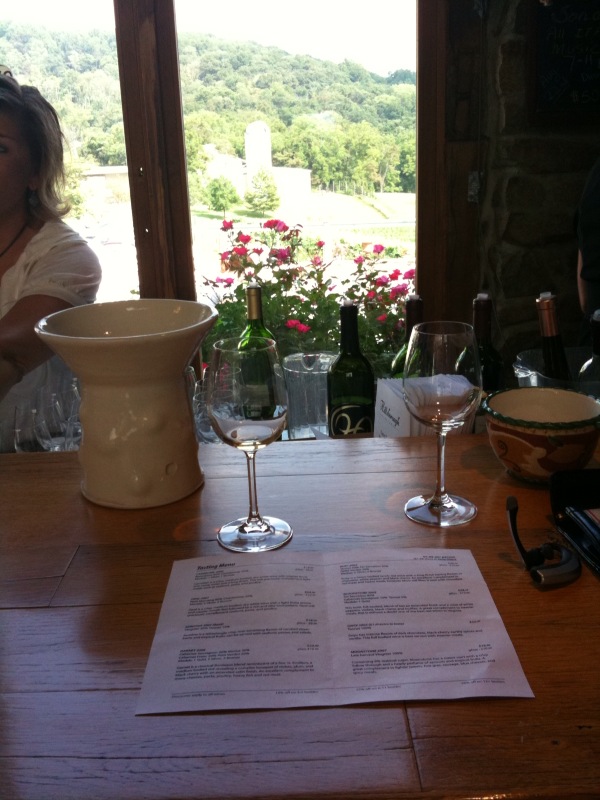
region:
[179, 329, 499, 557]
Wine glasses on table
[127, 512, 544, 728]
Wine menu on the table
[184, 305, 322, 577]
Wine glass on the table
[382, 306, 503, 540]
Wine glass on the table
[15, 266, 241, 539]
Spit bucket on the table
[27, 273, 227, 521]
White spit bucket on table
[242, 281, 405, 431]
bottles of wine behind glasses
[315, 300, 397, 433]
bottle of wine with black label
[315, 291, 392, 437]
bottle of wine behind glasses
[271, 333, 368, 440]
Pitcher of water behind glasses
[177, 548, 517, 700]
white paper menu on table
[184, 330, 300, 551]
crystal wine glass on table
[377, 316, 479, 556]
crystal wine glass on table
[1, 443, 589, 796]
wooden table inside of restaurant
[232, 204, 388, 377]
pink flowers by window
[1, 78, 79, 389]
woman sitting in restaurant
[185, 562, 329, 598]
small black writing on menu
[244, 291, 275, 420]
green wine bottle by table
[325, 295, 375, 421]
green wine bottle by table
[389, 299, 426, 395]
green wine bottle by table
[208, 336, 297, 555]
the wine glass on the table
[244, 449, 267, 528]
the stem of the glass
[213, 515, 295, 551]
the base of the wine glass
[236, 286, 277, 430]
the wine bottle behind the wine glass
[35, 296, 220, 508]
the white vase on the table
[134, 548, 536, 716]
the white menu on the table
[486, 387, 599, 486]
the bowl on the table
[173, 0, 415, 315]
the window behind the table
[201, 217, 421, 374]
the plant outside of the window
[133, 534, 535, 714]
A menu on the table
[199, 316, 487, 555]
Two empty wine glasses on the table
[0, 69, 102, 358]
Blonde-haired woman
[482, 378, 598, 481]
A bowl on the table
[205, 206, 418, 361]
Pink flowers in the window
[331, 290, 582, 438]
Four bottles of wine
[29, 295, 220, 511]
Empty white vase on the table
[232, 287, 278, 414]
Open bottle of wine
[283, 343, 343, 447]
Glass pitcher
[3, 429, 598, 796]
Wooden countertop